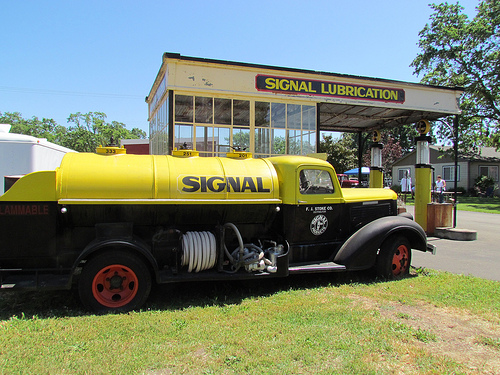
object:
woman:
[434, 175, 448, 201]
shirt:
[435, 179, 444, 189]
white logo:
[299, 203, 343, 238]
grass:
[0, 270, 495, 370]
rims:
[74, 249, 159, 317]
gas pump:
[359, 120, 386, 192]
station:
[140, 52, 472, 239]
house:
[389, 143, 499, 197]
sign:
[252, 75, 410, 104]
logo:
[178, 176, 270, 196]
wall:
[168, 60, 464, 118]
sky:
[0, 0, 499, 147]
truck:
[0, 135, 436, 314]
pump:
[409, 115, 435, 242]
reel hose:
[174, 228, 224, 277]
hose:
[186, 230, 218, 271]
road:
[393, 200, 500, 284]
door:
[296, 163, 343, 263]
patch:
[331, 283, 498, 372]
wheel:
[77, 244, 147, 313]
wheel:
[376, 232, 411, 280]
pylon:
[367, 166, 384, 188]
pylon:
[413, 164, 431, 234]